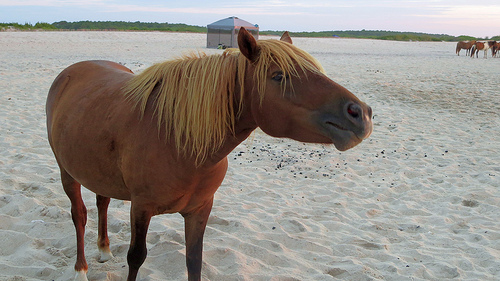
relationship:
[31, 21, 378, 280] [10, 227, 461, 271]
horse standing in sand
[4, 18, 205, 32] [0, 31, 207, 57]
trees above sand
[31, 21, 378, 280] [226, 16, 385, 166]
horse has head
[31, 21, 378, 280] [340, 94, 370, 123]
horse has nose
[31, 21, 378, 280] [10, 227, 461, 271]
horse standing on sand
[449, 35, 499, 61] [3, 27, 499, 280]
horses are on beach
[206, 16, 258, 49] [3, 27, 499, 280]
center on beach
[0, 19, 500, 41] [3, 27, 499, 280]
hill behind beach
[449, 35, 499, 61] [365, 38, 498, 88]
horses in sand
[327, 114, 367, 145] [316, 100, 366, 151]
mouth seen a part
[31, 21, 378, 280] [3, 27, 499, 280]
horse standing on beach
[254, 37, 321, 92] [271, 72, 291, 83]
hair over eye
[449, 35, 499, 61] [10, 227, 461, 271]
horses standing on sand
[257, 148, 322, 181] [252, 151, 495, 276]
specs are on sand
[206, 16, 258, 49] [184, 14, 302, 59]
center in center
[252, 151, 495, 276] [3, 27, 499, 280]
footprints in sand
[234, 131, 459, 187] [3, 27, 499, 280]
trash in sand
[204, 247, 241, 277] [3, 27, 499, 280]
footprint in sand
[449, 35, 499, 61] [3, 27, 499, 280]
horses standing together on sand